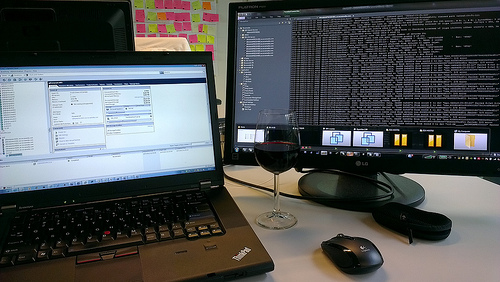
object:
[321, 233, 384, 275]
black mouse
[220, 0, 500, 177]
computer screen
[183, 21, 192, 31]
post note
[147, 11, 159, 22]
sticky note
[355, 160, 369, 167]
logo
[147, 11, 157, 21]
post it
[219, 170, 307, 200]
black cord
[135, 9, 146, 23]
post it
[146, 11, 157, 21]
post it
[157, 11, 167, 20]
post it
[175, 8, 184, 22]
post it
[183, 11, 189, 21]
post it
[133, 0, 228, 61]
wall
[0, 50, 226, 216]
screen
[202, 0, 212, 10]
note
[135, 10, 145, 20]
post it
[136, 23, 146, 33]
post it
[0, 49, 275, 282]
computer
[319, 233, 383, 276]
mouse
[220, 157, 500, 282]
desk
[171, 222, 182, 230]
button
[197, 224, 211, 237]
button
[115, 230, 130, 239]
button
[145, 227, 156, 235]
button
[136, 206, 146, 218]
button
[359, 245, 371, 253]
logo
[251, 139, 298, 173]
wine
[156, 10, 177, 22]
post it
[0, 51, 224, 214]
monitor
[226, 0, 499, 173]
monitor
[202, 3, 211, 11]
sticky note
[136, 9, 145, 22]
sticky note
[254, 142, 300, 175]
liquid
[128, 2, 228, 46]
notes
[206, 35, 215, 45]
sticky note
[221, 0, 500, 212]
screen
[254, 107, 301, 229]
glass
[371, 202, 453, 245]
case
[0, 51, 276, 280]
laptop